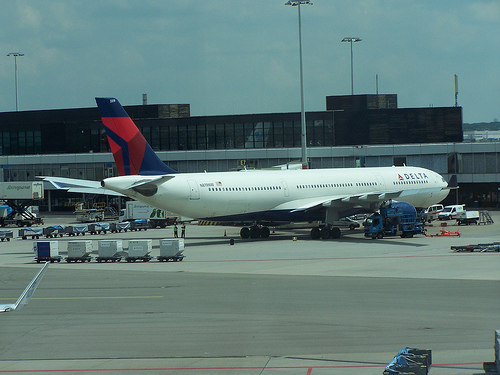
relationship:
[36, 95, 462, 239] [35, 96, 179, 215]
plane has a tail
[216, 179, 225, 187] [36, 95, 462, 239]
flag on plane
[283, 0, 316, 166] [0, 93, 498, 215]
pole by airport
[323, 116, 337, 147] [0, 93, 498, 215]
window on airport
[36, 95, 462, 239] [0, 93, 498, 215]
plane by airport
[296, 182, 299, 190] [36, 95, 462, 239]
small window on plane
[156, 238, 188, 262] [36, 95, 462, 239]
cart next to plane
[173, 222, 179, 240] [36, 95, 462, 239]
person below plane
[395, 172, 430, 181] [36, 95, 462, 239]
logo on plane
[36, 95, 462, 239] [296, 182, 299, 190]
plane has small window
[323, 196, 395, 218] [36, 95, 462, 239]
engine on plane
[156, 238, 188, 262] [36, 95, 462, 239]
cart by plane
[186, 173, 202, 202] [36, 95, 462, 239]
door on plane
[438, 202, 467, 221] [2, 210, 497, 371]
van on tarmac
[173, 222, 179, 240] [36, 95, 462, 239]
person under plane